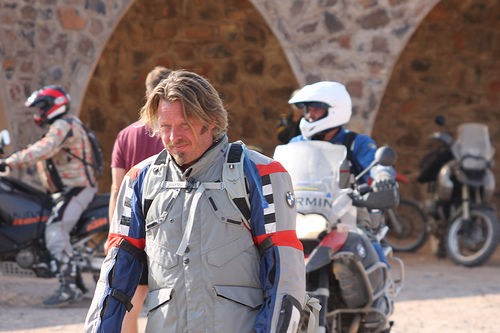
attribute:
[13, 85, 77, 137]
helmet — black and red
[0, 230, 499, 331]
ground — brown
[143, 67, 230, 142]
hair — brown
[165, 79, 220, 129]
hair — short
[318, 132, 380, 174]
outfit — gray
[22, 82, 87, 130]
helmet — Red, black, white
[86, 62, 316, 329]
man — blond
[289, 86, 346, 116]
helmet — white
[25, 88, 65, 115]
helmet — red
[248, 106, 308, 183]
wall — brown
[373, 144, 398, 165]
mirror — black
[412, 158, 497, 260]
motorcycle — gray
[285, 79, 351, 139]
helmet — white